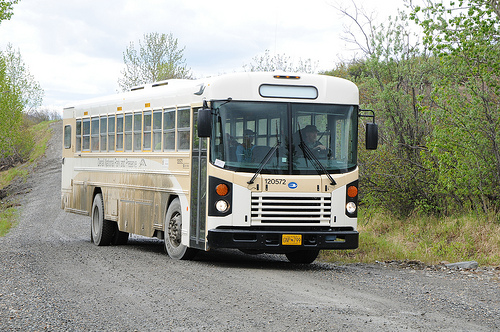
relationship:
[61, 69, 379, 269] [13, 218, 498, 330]
bus on road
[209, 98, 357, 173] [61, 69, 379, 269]
windshield on front of bus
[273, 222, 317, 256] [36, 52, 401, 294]
license plate on bus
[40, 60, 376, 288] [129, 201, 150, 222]
bus covered with mud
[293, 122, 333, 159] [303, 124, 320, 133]
driver wearing hat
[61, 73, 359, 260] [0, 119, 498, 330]
bus driving down road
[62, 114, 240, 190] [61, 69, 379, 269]
passenger windows on bus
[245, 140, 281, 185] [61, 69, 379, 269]
windshield wiper of bus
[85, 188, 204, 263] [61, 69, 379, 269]
wheels of bus